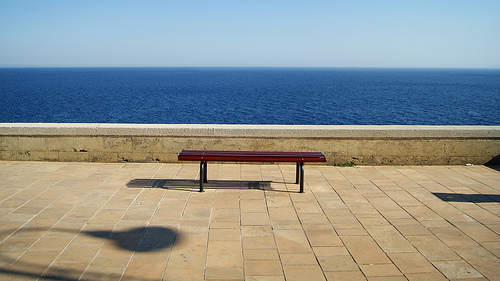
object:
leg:
[297, 163, 305, 193]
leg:
[293, 162, 300, 184]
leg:
[201, 159, 208, 183]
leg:
[197, 163, 204, 192]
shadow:
[0, 256, 171, 281]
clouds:
[277, 12, 323, 60]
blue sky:
[1, 0, 26, 64]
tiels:
[365, 171, 442, 202]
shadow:
[25, 223, 183, 254]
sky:
[445, 0, 497, 29]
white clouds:
[425, 55, 477, 66]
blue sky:
[181, 51, 358, 64]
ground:
[3, 158, 498, 278]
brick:
[318, 202, 350, 216]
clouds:
[460, 3, 500, 62]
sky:
[432, 50, 500, 69]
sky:
[91, 6, 180, 43]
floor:
[198, 198, 434, 279]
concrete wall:
[1, 123, 500, 142]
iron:
[196, 162, 303, 193]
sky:
[138, 12, 251, 47]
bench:
[177, 150, 327, 194]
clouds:
[58, 0, 423, 9]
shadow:
[125, 178, 301, 193]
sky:
[45, 6, 83, 69]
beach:
[0, 65, 500, 116]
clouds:
[427, 6, 455, 45]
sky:
[276, 2, 370, 33]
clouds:
[0, 1, 271, 61]